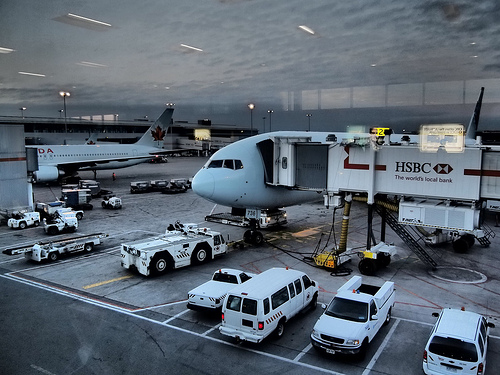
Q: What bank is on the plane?
A: HSBC.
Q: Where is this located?
A: Airport.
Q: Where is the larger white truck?
A: Right of van.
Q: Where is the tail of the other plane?
A: Left of the main plane.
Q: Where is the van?
A: Between the two trucks.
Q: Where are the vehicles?
A: Parked beside the planes.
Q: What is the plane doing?
A: Unloading.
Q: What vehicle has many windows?
A: Van.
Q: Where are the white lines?
A: On pavement between vehicles.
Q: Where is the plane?
A: Airport.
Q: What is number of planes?
A: Two.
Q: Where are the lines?
A: On the ground.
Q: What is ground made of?
A: Concrete.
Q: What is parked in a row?
A: White vehicles.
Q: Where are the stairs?
A: Under plane.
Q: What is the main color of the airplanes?
A: White.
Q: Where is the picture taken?
A: Airport hangar.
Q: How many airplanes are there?
A: Two.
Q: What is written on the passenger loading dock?
A: HSBC.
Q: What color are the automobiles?
A: White.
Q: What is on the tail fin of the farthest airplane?
A: Red maple leaf.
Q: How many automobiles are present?
A: Four.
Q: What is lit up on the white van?
A: It's tail lights.